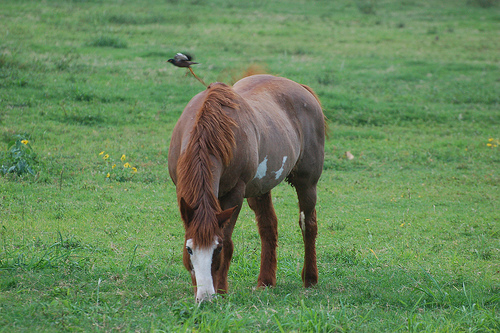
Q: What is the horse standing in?
A: Grass.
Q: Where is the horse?
A: In a field.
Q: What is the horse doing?
A: Eating grass.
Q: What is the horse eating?
A: Grass.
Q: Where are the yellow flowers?
A: In the field.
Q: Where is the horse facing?
A: The camera.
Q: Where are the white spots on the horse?
A: On the left chest.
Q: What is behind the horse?
A: A grassy field.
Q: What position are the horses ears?
A: Pointing upwards and alerted.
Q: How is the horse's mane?
A: Unkempt pointing in both directions.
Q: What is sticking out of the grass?
A: Yellow flowers.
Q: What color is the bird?
A: Black.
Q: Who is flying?
A: A bird.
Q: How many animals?
A: Two.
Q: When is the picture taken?
A: Daytime.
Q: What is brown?
A: A horse.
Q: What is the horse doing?
A: Grazing.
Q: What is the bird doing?
A: Flying.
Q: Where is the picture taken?
A: In a field.